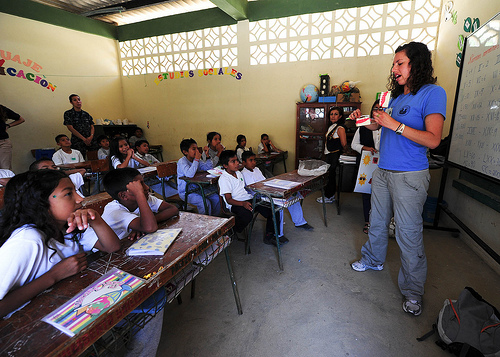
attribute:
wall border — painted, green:
[0, 1, 412, 41]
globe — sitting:
[296, 81, 323, 103]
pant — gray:
[357, 167, 432, 302]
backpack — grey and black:
[413, 286, 498, 356]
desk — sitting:
[245, 160, 330, 270]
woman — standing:
[316, 105, 347, 203]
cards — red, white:
[351, 86, 393, 133]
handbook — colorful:
[36, 262, 151, 337]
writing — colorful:
[8, 49, 60, 98]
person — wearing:
[61, 90, 98, 153]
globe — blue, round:
[293, 76, 334, 111]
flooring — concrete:
[165, 155, 496, 347]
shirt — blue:
[375, 81, 448, 175]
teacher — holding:
[336, 55, 455, 271]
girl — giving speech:
[351, 50, 451, 320]